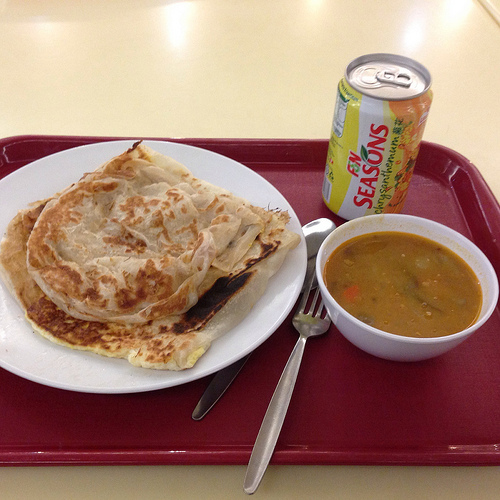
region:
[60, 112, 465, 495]
a tray of foods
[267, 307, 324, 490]
the fork is silver in color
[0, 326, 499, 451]
the tray is maroon in color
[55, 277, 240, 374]
the plate is white in olor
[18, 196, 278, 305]
the pancakes are brown white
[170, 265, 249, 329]
part of the pancake is burnt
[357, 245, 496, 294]
the soup is brown in color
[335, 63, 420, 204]
the drink is on the tray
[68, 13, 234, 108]
the wall is light brown in color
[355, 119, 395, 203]
the words are written in red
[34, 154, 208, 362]
This is a tortilla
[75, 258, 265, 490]
This is naan bread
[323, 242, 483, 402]
This is indian soup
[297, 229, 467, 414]
The soup is indian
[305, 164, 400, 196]
This is a can of soda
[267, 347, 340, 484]
This is a utensil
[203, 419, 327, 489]
This is a fork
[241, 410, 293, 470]
The fork is silver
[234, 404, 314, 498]
The fork is made of metal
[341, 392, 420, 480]
The tray is red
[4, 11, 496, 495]
Interior view, with artificial lights, season, not known.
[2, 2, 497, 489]
Interior building, showing close up of edibles, probably daytime.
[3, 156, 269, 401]
Round, white plate with food.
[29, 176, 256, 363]
Bready item, probably pancakes.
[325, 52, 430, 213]
Yellow, pull-tab can with drink in it.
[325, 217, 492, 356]
White bowl, with vegetable soup.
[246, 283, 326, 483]
Fork, between plate and bowl.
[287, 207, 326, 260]
Spoon, near can.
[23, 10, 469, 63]
Wall, showing fluorescent light halos.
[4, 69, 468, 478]
Food tray, showing utensils, food and containers.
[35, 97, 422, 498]
a tray full of food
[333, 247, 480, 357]
the soup is brown in color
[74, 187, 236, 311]
the pancakes are white brown in color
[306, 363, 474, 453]
the tray is maroon in color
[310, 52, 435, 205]
the drink is closed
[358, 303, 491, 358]
the pot is white in color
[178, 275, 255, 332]
the pancake is burnt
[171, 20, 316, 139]
the wall is lime white in color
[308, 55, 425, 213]
The can is yellow.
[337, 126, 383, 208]
The lettering is red.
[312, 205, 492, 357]
The soup is in a bowl.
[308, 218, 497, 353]
The bowl is white.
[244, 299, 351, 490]
The fork is on the tray.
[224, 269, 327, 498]
The fork is silver.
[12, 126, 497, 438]
The food is on a tray.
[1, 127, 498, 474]
The tray is red.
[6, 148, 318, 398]
The plate is white.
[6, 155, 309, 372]
The food is on the plate.